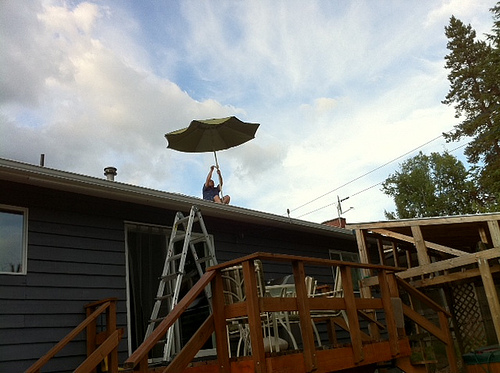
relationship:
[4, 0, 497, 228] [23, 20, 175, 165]
sky has clouds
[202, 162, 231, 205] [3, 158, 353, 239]
man sitting on top of roof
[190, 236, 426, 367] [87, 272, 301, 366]
railing of deck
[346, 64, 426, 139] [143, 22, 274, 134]
clouds in sky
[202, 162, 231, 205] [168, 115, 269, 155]
man holding up umbrella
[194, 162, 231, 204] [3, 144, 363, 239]
man sitting on roof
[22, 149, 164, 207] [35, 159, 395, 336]
gutter hanging over building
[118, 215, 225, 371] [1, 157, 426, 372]
doors built into wall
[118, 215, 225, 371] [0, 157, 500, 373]
doors built into building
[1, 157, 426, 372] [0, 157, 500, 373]
wall supporting building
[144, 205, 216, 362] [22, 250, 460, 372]
ladder standing on deck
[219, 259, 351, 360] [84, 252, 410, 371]
furniture sitting on wooden deck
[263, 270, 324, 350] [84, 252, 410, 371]
furniture sitting on wooden deck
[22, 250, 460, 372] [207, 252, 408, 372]
deck with railing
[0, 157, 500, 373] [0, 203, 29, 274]
building white window frame